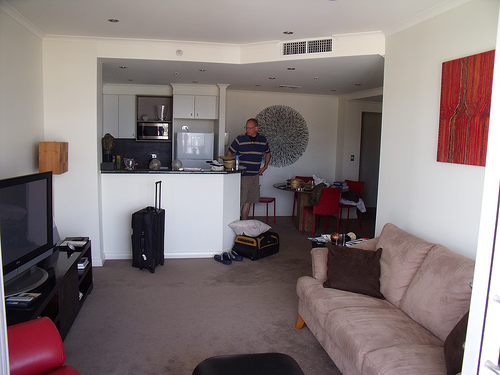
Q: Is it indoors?
A: Yes, it is indoors.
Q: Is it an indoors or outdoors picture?
A: It is indoors.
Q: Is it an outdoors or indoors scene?
A: It is indoors.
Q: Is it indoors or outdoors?
A: It is indoors.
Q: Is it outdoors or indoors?
A: It is indoors.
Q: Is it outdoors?
A: No, it is indoors.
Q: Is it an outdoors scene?
A: No, it is indoors.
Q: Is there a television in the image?
A: Yes, there is a television.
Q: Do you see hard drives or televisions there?
A: Yes, there is a television.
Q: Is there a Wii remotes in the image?
A: No, there are no Wii controllers.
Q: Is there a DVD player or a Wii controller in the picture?
A: No, there are no Wii controllers or DVD players.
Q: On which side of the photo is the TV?
A: The TV is on the left of the image.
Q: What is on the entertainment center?
A: The television is on the entertainment center.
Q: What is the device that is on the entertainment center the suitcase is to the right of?
A: The device is a television.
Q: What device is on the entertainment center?
A: The device is a television.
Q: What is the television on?
A: The television is on the entertainment center.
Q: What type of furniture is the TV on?
A: The TV is on the entertainment center.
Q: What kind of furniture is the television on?
A: The TV is on the entertainment center.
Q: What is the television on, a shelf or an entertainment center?
A: The television is on an entertainment center.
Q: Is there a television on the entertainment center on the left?
A: Yes, there is a television on the entertainment center.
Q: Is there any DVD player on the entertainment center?
A: No, there is a television on the entertainment center.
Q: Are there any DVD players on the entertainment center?
A: No, there is a television on the entertainment center.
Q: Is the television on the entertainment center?
A: Yes, the television is on the entertainment center.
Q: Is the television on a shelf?
A: No, the television is on the entertainment center.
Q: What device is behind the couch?
A: The device is a television.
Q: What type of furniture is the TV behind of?
A: The TV is behind the couch.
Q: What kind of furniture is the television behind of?
A: The TV is behind the couch.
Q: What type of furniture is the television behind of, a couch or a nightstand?
A: The television is behind a couch.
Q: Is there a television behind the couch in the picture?
A: Yes, there is a television behind the couch.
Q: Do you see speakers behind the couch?
A: No, there is a television behind the couch.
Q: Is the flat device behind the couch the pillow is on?
A: Yes, the TV is behind the couch.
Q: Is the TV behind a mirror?
A: No, the TV is behind the couch.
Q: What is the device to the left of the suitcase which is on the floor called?
A: The device is a television.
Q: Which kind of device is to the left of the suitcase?
A: The device is a television.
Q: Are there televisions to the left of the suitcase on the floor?
A: Yes, there is a television to the left of the suitcase.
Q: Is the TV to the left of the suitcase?
A: Yes, the TV is to the left of the suitcase.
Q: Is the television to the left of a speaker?
A: No, the television is to the left of the suitcase.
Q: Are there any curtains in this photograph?
A: No, there are no curtains.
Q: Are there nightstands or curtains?
A: No, there are no curtains or nightstands.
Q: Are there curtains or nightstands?
A: No, there are no curtains or nightstands.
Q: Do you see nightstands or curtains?
A: No, there are no curtains or nightstands.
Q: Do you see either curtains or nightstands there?
A: No, there are no curtains or nightstands.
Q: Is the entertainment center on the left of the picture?
A: Yes, the entertainment center is on the left of the image.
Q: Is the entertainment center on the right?
A: No, the entertainment center is on the left of the image.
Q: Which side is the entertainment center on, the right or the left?
A: The entertainment center is on the left of the image.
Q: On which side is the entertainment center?
A: The entertainment center is on the left of the image.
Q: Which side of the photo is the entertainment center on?
A: The entertainment center is on the left of the image.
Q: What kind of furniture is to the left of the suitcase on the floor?
A: The piece of furniture is an entertainment center.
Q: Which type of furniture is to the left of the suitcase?
A: The piece of furniture is an entertainment center.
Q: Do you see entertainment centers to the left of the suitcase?
A: Yes, there is an entertainment center to the left of the suitcase.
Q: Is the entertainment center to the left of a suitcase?
A: Yes, the entertainment center is to the left of a suitcase.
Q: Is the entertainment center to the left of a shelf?
A: No, the entertainment center is to the left of a suitcase.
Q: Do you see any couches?
A: Yes, there is a couch.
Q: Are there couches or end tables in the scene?
A: Yes, there is a couch.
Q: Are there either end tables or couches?
A: Yes, there is a couch.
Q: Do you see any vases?
A: No, there are no vases.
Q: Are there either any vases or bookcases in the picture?
A: No, there are no vases or bookcases.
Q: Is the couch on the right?
A: Yes, the couch is on the right of the image.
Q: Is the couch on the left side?
A: No, the couch is on the right of the image.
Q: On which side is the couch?
A: The couch is on the right of the image.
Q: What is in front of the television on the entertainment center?
A: The couch is in front of the TV.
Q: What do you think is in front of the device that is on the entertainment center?
A: The couch is in front of the TV.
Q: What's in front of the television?
A: The couch is in front of the TV.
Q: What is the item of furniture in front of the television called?
A: The piece of furniture is a couch.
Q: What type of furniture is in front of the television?
A: The piece of furniture is a couch.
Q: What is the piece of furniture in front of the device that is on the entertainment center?
A: The piece of furniture is a couch.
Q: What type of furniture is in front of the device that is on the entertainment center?
A: The piece of furniture is a couch.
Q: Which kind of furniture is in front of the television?
A: The piece of furniture is a couch.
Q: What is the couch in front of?
A: The couch is in front of the TV.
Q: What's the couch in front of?
A: The couch is in front of the TV.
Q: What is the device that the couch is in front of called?
A: The device is a television.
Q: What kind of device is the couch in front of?
A: The couch is in front of the TV.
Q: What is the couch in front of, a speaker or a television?
A: The couch is in front of a television.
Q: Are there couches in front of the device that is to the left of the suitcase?
A: Yes, there is a couch in front of the television.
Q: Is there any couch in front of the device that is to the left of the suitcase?
A: Yes, there is a couch in front of the television.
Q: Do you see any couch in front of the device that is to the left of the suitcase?
A: Yes, there is a couch in front of the television.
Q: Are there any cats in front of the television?
A: No, there is a couch in front of the television.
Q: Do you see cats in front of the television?
A: No, there is a couch in front of the television.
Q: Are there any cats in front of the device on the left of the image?
A: No, there is a couch in front of the television.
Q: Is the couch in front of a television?
A: Yes, the couch is in front of a television.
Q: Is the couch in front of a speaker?
A: No, the couch is in front of a television.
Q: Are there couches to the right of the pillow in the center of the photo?
A: Yes, there is a couch to the right of the pillow.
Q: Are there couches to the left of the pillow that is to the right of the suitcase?
A: No, the couch is to the right of the pillow.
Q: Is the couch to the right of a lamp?
A: No, the couch is to the right of the pillow.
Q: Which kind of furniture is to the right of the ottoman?
A: The piece of furniture is a couch.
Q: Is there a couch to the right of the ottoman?
A: Yes, there is a couch to the right of the ottoman.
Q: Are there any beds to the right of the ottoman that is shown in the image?
A: No, there is a couch to the right of the ottoman.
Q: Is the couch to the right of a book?
A: No, the couch is to the right of the ottoman.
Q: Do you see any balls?
A: No, there are no balls.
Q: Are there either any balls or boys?
A: No, there are no balls or boys.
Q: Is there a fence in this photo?
A: No, there are no fences.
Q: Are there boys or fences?
A: No, there are no fences or boys.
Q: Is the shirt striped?
A: Yes, the shirt is striped.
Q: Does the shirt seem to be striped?
A: Yes, the shirt is striped.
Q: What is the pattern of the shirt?
A: The shirt is striped.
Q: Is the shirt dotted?
A: No, the shirt is striped.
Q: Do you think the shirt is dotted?
A: No, the shirt is striped.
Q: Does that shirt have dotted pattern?
A: No, the shirt is striped.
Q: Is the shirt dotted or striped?
A: The shirt is striped.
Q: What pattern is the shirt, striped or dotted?
A: The shirt is striped.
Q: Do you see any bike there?
A: No, there are no bikes.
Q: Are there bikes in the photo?
A: No, there are no bikes.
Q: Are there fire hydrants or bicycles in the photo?
A: No, there are no bicycles or fire hydrants.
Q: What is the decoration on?
A: The decoration is on the wall.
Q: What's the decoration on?
A: The decoration is on the wall.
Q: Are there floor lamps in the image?
A: No, there are no floor lamps.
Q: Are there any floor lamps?
A: No, there are no floor lamps.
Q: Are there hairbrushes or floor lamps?
A: No, there are no floor lamps or hairbrushes.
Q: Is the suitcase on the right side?
A: No, the suitcase is on the left of the image.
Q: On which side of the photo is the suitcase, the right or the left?
A: The suitcase is on the left of the image.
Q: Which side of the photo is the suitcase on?
A: The suitcase is on the left of the image.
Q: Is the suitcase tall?
A: Yes, the suitcase is tall.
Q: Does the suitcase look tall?
A: Yes, the suitcase is tall.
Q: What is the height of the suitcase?
A: The suitcase is tall.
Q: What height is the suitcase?
A: The suitcase is tall.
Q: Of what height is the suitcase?
A: The suitcase is tall.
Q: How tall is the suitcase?
A: The suitcase is tall.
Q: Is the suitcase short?
A: No, the suitcase is tall.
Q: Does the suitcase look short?
A: No, the suitcase is tall.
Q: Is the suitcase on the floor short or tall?
A: The suitcase is tall.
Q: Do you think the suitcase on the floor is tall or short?
A: The suitcase is tall.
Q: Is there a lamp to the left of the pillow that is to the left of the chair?
A: No, there is a suitcase to the left of the pillow.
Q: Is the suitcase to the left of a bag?
A: No, the suitcase is to the left of the pillow.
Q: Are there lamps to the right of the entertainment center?
A: No, there is a suitcase to the right of the entertainment center.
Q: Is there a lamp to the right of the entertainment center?
A: No, there is a suitcase to the right of the entertainment center.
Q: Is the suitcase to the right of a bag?
A: No, the suitcase is to the right of an entertainment center.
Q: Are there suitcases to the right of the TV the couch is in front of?
A: Yes, there is a suitcase to the right of the TV.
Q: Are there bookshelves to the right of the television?
A: No, there is a suitcase to the right of the television.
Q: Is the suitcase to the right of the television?
A: Yes, the suitcase is to the right of the television.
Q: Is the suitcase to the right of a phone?
A: No, the suitcase is to the right of the television.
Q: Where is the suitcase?
A: The suitcase is on the floor.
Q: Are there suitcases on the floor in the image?
A: Yes, there is a suitcase on the floor.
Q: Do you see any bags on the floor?
A: No, there is a suitcase on the floor.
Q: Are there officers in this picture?
A: No, there are no officers.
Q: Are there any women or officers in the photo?
A: No, there are no officers or women.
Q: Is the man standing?
A: Yes, the man is standing.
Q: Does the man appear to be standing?
A: Yes, the man is standing.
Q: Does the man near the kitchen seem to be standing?
A: Yes, the man is standing.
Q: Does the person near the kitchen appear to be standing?
A: Yes, the man is standing.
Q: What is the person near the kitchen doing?
A: The man is standing.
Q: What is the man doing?
A: The man is standing.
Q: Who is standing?
A: The man is standing.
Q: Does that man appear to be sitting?
A: No, the man is standing.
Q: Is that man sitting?
A: No, the man is standing.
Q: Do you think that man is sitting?
A: No, the man is standing.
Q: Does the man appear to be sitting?
A: No, the man is standing.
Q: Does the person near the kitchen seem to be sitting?
A: No, the man is standing.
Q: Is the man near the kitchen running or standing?
A: The man is standing.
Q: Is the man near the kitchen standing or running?
A: The man is standing.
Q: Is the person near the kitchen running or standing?
A: The man is standing.